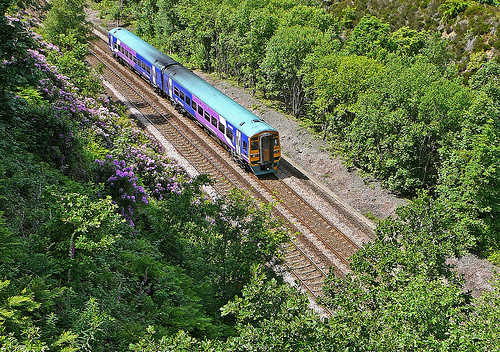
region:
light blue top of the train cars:
[109, 20, 266, 140]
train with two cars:
[100, 19, 282, 172]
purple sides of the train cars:
[108, 32, 256, 164]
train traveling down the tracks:
[103, 21, 293, 182]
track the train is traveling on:
[76, 15, 371, 278]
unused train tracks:
[87, 42, 357, 332]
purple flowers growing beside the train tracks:
[11, 11, 197, 228]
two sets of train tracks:
[71, 14, 368, 314]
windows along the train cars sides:
[110, 34, 246, 154]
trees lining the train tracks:
[9, 2, 494, 342]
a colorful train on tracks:
[97, 22, 317, 189]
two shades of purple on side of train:
[108, 34, 241, 162]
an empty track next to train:
[86, 49, 378, 344]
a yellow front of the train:
[249, 124, 297, 184]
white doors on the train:
[230, 123, 256, 165]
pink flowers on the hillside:
[24, 41, 187, 236]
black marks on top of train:
[148, 46, 205, 96]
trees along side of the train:
[142, 3, 497, 242]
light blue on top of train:
[110, 24, 275, 147]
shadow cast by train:
[267, 142, 318, 207]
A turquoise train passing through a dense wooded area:
[100, 18, 294, 182]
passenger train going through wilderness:
[89, 33, 280, 151]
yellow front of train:
[244, 123, 276, 170]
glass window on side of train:
[223, 126, 233, 138]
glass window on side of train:
[216, 121, 224, 135]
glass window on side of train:
[210, 115, 219, 132]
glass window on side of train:
[200, 108, 212, 120]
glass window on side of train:
[192, 95, 199, 112]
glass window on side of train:
[177, 87, 188, 102]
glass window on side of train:
[126, 51, 133, 60]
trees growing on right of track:
[219, 4, 496, 198]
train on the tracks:
[95, 18, 305, 188]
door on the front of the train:
[258, 133, 275, 167]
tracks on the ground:
[271, 193, 351, 253]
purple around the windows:
[192, 98, 219, 134]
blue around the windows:
[172, 84, 192, 116]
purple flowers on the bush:
[106, 151, 178, 209]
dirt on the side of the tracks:
[317, 153, 337, 182]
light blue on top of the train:
[196, 83, 220, 103]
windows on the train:
[173, 86, 213, 121]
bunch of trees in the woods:
[45, 221, 142, 296]